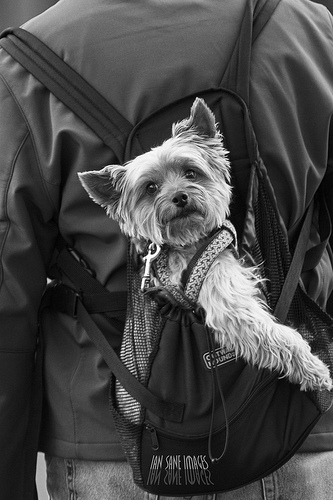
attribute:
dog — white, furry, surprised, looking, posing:
[77, 98, 330, 395]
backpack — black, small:
[6, 3, 330, 498]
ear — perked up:
[169, 98, 229, 141]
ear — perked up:
[76, 162, 122, 205]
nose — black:
[169, 193, 192, 210]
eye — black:
[183, 167, 200, 181]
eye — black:
[142, 181, 159, 193]